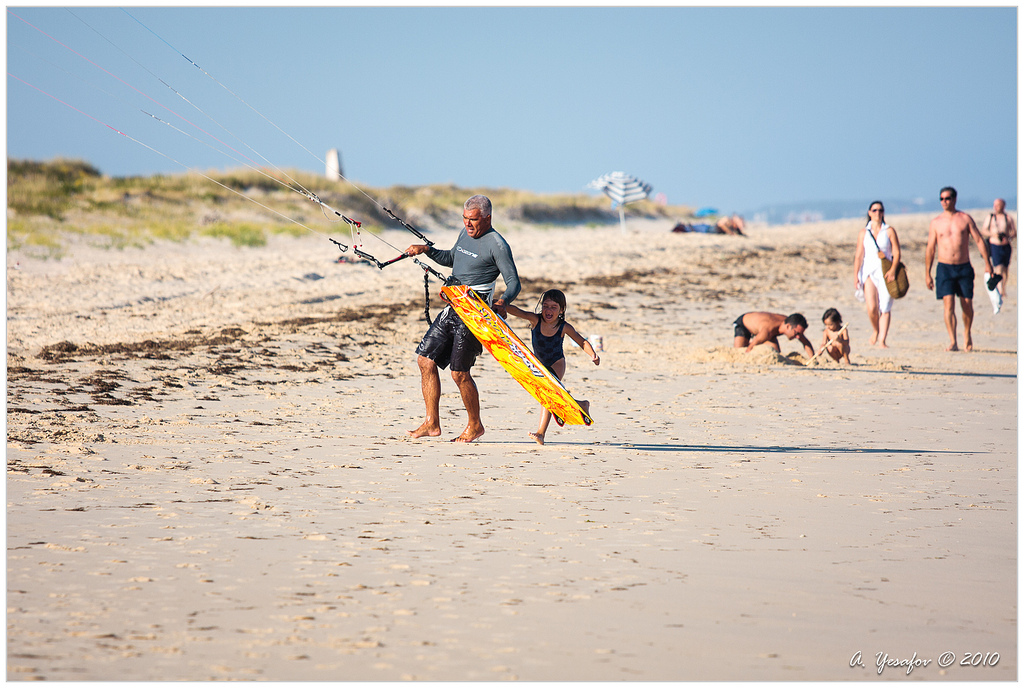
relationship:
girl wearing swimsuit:
[499, 284, 595, 441] [514, 312, 581, 373]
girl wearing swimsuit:
[489, 283, 606, 448] [532, 309, 576, 385]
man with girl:
[400, 195, 518, 442] [494, 290, 611, 440]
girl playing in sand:
[815, 305, 851, 369] [14, 209, 1017, 684]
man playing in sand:
[731, 306, 815, 368] [14, 209, 1017, 684]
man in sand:
[731, 311, 819, 367] [14, 209, 1017, 684]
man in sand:
[400, 195, 521, 442] [14, 209, 1017, 684]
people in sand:
[854, 192, 899, 344] [14, 209, 1017, 684]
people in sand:
[978, 192, 1020, 306] [14, 209, 1017, 684]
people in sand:
[920, 186, 1004, 358] [14, 209, 1017, 684]